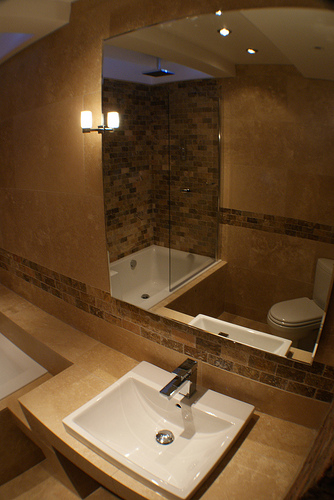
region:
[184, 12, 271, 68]
lights on the ceiling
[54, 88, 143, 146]
the light is on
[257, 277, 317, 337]
the lid is closed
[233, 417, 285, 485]
the counter is beige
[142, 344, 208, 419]
the faucet is square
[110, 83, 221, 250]
the shower is made with bricks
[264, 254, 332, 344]
a white toilet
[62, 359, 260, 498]
a white bathroom sink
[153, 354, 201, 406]
a bathroom sink faucet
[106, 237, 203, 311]
part of a white bathtub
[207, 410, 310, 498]
part of a brown sink counter top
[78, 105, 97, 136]
a small wall light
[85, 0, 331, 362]
a large wall mirror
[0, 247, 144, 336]
multicolored wall tile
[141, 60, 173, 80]
part of a shower head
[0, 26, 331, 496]
a bathroom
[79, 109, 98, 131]
a light on the wall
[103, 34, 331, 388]
the mirror in the bathroom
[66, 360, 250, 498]
the sink in the bathroom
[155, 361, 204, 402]
the faucet on the sink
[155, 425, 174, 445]
the silver drain in the sink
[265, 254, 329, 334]
a white toilet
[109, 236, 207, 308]
a bath tub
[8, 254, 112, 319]
tile back splash on the wall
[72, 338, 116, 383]
the brown counter top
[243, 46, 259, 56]
recessed light in the ceiling of the bathroom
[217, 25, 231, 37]
recessed light in the ceiling of the bathroom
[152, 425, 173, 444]
silver drain on the bathroom sink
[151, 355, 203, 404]
silver faucet on the bathroom sink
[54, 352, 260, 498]
white sink in the bathroom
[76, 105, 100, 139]
wall mounted light in the bathroom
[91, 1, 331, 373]
silver mirror with no frame in the bathroom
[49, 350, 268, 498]
white porcelain sink in the bathroom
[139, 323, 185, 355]
small piece of tile in the bathroom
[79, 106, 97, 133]
a small light in a bathroom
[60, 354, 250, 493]
a porcelain sink in a bathroom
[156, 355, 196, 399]
the faucet of a sink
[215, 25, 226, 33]
a ceiling light in a bathroom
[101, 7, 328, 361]
a large mirror in a bathroom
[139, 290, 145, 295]
a drain in a shower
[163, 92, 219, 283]
a glass shower door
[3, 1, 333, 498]
a contemporary looking bathroom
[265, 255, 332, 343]
a commode in a bathroom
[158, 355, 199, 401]
A faucet on a sink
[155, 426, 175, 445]
A drain in a sink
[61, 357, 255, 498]
A sink in a bathroom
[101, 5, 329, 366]
A mirror in a bathroom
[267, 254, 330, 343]
A toilet in a bathroom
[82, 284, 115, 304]
a tile in a wall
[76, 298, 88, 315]
a tile in a wall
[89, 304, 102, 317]
a tile in a wall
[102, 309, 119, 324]
a tile in a wall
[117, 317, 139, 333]
a tile in a wall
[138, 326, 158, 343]
a tile in a wall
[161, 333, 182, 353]
a tile in a wall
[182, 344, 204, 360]
a tile in a wall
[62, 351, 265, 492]
square white ceramic sink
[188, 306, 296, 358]
white sink reflection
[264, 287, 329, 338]
white ceramic toilet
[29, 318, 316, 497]
tan brown bathroom counte r